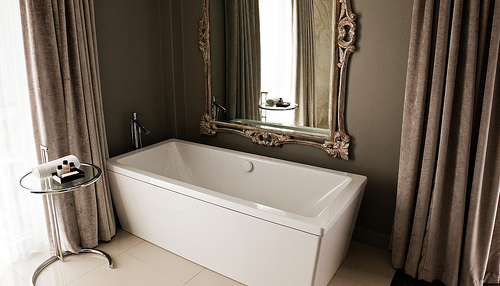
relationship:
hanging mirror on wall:
[208, 0, 338, 137] [151, 0, 428, 272]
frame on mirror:
[323, 2, 381, 176] [190, 6, 384, 170]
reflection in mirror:
[232, 86, 324, 119] [209, 1, 331, 133]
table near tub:
[19, 141, 115, 283] [135, 91, 374, 252]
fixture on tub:
[127, 110, 149, 153] [105, 136, 375, 285]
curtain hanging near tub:
[15, 0, 118, 260] [105, 136, 375, 285]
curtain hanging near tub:
[387, 0, 499, 282] [105, 136, 375, 285]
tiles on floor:
[6, 231, 398, 285] [8, 228, 413, 283]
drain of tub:
[237, 151, 284, 185] [105, 136, 375, 285]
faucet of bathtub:
[128, 109, 146, 146] [104, 133, 369, 284]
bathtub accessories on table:
[106, 139, 367, 286] [15, 137, 131, 266]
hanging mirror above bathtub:
[208, 0, 338, 137] [106, 139, 367, 286]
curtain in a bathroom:
[390, 0, 500, 286] [0, 3, 495, 284]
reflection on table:
[258, 98, 298, 111] [229, 86, 319, 126]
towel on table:
[30, 144, 88, 181] [0, 132, 129, 252]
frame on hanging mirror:
[197, 0, 356, 161] [208, 0, 338, 137]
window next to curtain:
[0, 0, 51, 280] [15, 0, 118, 260]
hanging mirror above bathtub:
[208, 0, 338, 137] [104, 133, 369, 284]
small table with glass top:
[1, 147, 148, 284] [8, 142, 124, 207]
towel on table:
[32, 155, 80, 179] [20, 156, 114, 284]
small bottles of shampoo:
[30, 156, 88, 198] [48, 158, 88, 178]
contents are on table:
[29, 150, 86, 182] [20, 156, 114, 284]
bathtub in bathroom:
[104, 133, 369, 284] [0, 3, 495, 284]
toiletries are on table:
[44, 158, 86, 184] [2, 143, 117, 280]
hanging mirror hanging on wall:
[208, 0, 338, 137] [175, 1, 412, 248]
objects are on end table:
[54, 152, 82, 179] [24, 143, 125, 277]